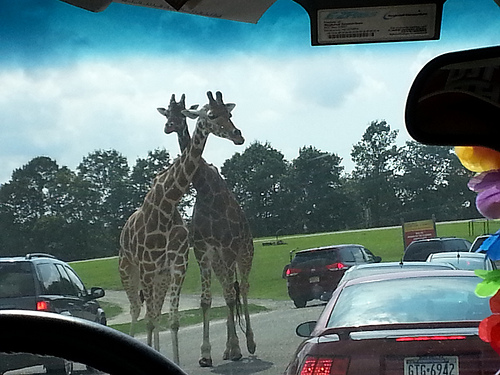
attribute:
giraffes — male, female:
[117, 89, 261, 364]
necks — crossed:
[145, 130, 229, 205]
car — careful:
[403, 239, 463, 256]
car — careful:
[426, 251, 491, 271]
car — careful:
[285, 242, 378, 304]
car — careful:
[295, 271, 499, 368]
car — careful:
[5, 257, 108, 328]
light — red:
[299, 353, 339, 371]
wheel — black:
[280, 289, 314, 319]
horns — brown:
[202, 89, 214, 104]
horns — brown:
[212, 89, 223, 106]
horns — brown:
[165, 93, 176, 108]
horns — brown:
[177, 92, 187, 105]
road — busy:
[218, 320, 290, 367]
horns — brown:
[203, 82, 227, 97]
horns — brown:
[163, 90, 188, 101]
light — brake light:
[35, 298, 50, 312]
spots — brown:
[140, 220, 185, 270]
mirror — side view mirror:
[88, 287, 105, 299]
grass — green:
[268, 239, 280, 261]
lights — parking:
[278, 263, 355, 283]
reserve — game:
[31, 86, 471, 305]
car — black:
[285, 241, 384, 308]